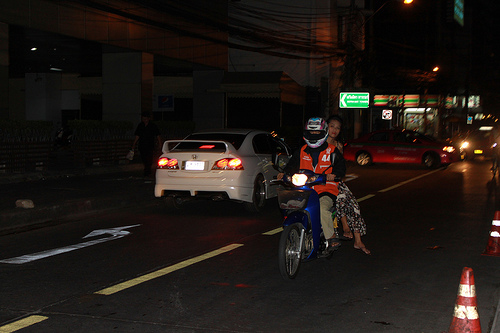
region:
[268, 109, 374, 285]
people ride on a motorcycle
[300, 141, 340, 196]
the man wearing an orange vest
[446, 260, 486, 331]
orange and white stiped traffic cone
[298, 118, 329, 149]
the white helmet of the motorcylist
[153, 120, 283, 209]
A white honda car on the road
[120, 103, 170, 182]
A person in black walking down the street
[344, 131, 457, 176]
a red car crossing the intersection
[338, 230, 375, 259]
the women in sandals on the back of the bike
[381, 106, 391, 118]
the white no truning sign on the post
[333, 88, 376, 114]
the green sign on the building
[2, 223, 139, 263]
the white arrow on the road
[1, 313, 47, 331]
the yellow line on the road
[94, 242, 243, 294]
the yellow line on the road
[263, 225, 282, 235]
the yellow line on the road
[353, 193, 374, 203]
the yellow line on the road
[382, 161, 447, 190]
the yellow line on the road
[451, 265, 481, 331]
the cone on the road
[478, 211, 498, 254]
the cone on the road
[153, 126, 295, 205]
the car on the road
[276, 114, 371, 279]
the people on a motorcycle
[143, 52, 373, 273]
motorcycle and car going in opposite directions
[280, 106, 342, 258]
driver wearing helmet and orange vest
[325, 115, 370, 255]
passenger seated sideways in long skirt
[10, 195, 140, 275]
white arrow on black road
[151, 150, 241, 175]
rear lights shining red and yellow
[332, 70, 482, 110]
traffic and business signs in row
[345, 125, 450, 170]
red car perpendicular to road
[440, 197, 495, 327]
orange and white safety cones on side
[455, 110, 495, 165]
headlights shining on dark street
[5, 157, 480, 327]
broker yellow line down street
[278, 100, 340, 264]
this is a person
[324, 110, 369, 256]
this is a person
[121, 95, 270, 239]
this is a car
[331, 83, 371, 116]
this is a sign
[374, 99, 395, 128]
this is a sign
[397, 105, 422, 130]
this is a sign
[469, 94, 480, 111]
this is a sign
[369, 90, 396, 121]
this is a sign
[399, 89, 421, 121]
this is a sign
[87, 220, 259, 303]
this is a line on the road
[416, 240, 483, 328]
this is a sign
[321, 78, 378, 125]
this is a sign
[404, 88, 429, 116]
this is a sign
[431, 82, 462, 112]
this is a sign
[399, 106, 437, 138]
this is a sign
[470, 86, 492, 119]
this is a sign